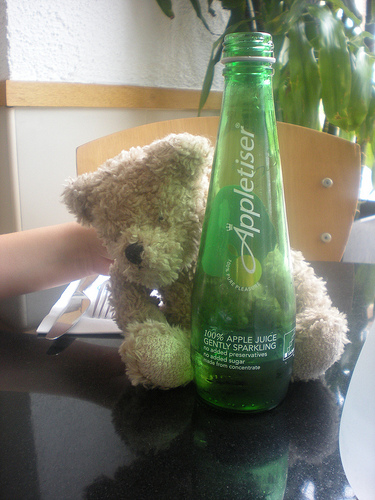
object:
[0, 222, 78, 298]
person's arm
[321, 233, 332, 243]
rivets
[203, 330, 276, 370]
words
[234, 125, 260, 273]
word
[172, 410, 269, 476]
surface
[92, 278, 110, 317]
fork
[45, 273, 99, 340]
knife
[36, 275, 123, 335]
napkin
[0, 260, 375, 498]
counter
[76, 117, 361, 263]
seat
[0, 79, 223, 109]
strip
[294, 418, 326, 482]
surface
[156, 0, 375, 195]
plant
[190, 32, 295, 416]
bottle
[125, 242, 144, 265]
nose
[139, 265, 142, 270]
mouth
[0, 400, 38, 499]
surface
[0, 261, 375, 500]
table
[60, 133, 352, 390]
bear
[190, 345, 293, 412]
apple juice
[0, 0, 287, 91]
wall